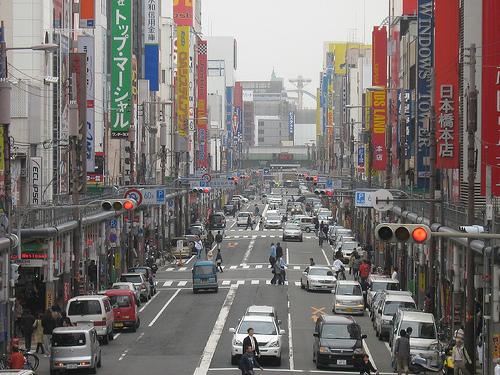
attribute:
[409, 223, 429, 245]
streetlight — Red  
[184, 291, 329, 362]
car — white 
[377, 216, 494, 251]
light — Red 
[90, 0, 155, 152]
sign — Green 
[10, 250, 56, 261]
sign — electric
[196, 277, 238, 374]
traffic line — White 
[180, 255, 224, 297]
van — Blue 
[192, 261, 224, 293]
minivan — teal, gray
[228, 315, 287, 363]
vehicle — White 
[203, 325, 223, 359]
line — solid white 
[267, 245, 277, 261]
shirt — Dark blue 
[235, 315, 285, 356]
car — White 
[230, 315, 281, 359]
car — white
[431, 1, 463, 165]
sign — red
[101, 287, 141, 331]
vehicle — red